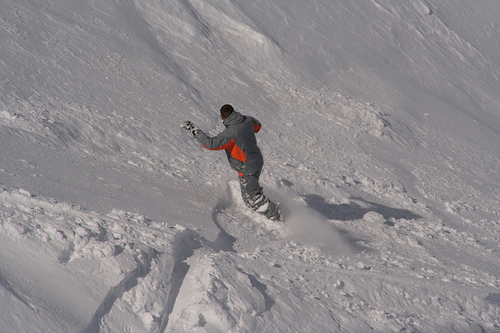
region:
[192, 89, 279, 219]
snowboarder wearing gray and orange jacket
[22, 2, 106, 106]
white snow on mountain side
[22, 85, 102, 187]
white snow on mountain side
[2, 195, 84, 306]
white snow on mountain side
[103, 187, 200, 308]
white snow on mountain side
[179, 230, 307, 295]
white snow on mountain side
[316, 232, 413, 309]
white snow on mountain side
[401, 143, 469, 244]
white snow on mountain side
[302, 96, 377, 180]
white snow on mountain side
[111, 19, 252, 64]
white snow on mountain side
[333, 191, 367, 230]
part of a shade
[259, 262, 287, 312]
paert of a snow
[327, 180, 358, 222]
part of a shade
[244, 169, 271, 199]
part of a troiser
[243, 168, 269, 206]
part of a trouser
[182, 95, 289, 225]
young man snow boarding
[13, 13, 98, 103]
white clouds in blue sky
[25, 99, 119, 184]
white clouds in blue sky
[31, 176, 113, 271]
white clouds in blue sky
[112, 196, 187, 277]
white clouds in blue sky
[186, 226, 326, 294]
white clouds in blue sky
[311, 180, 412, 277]
white clouds in blue sky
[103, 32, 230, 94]
white clouds in blue sky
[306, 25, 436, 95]
white clouds in blue sky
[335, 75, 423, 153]
white clouds in blue sky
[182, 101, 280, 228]
Male snowboarder going down the mountain.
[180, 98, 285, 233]
Snowboarder riding downhill.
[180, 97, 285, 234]
Man riding on a snowboard.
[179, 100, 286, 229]
Snowboarder riding downhill on the snow.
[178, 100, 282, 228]
Man snowboarding on powerdy snow.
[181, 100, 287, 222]
Snowboarder wearing heavy jacket and snowboarding pants.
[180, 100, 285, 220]
Man snowboarding on a sunny, snowy mountain.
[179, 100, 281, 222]
Male snowboarder in the fresh mountain snow.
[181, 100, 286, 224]
Snowboarder wearing snowboard gear going down the mountain.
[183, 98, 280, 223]
Male snowboarder balancing on his board while going downhill.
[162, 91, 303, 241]
man snow boarding down mountain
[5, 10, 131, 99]
white snow on hill side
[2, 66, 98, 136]
white snow on hill side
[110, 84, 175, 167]
white snow on hill side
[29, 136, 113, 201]
white snow on hill side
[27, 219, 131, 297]
white snow on hill side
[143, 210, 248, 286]
white snow on hill side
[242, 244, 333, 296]
white snow on hill side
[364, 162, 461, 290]
white snow on hill side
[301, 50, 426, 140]
white snow on hill side